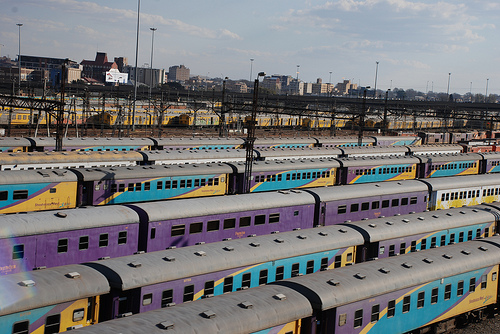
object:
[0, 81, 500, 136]
bridge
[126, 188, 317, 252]
train car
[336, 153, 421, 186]
train car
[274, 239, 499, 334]
train car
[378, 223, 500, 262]
purple gold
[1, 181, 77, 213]
purple gold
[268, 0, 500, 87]
cloud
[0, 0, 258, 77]
cloud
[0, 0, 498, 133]
outside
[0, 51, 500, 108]
buildings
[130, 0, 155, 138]
poles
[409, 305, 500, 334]
tracks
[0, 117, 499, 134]
tracks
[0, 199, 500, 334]
train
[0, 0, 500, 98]
sky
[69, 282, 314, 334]
grey trainroof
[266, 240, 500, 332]
grey trainroof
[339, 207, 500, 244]
grey trainroof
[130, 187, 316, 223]
grey trainroof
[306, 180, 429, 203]
grey trainroof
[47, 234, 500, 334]
train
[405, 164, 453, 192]
ground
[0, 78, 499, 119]
power lines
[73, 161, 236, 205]
train car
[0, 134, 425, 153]
train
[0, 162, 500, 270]
train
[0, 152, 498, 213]
train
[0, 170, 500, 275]
passenger train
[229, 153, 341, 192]
train car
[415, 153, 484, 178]
train car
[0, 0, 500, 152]
metropolis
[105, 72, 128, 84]
billboard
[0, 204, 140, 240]
roof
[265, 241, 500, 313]
roof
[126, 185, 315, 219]
roof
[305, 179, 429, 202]
roof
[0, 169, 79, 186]
roof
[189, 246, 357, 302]
stripe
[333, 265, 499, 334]
stripe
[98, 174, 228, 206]
stripe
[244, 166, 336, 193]
stripe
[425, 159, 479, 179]
stripe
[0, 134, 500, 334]
area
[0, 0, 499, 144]
background